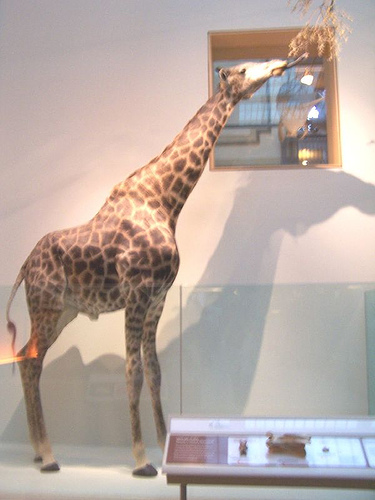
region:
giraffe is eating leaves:
[22, 58, 282, 451]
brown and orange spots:
[80, 110, 225, 329]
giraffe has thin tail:
[1, 249, 63, 336]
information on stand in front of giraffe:
[161, 412, 367, 466]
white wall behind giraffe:
[30, 66, 135, 177]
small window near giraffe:
[188, 30, 347, 165]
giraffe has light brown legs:
[122, 334, 168, 471]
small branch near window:
[268, 1, 333, 76]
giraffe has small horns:
[216, 68, 227, 83]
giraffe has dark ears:
[217, 73, 232, 110]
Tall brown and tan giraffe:
[3, 40, 318, 492]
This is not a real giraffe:
[5, 48, 311, 489]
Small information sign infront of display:
[148, 408, 370, 497]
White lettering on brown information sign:
[161, 422, 240, 472]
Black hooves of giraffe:
[24, 440, 165, 485]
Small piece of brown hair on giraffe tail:
[5, 319, 26, 366]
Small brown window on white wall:
[197, 16, 351, 196]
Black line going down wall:
[163, 283, 197, 415]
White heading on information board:
[163, 410, 373, 436]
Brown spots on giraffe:
[13, 64, 195, 452]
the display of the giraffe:
[1, 35, 316, 444]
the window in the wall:
[196, 28, 343, 176]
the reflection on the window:
[285, 65, 322, 113]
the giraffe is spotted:
[41, 148, 290, 307]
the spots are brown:
[33, 129, 204, 285]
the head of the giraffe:
[203, 43, 283, 121]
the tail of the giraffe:
[1, 283, 28, 370]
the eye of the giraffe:
[234, 67, 250, 78]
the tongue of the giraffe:
[282, 50, 316, 83]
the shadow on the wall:
[203, 196, 324, 278]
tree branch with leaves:
[283, 0, 352, 70]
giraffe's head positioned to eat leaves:
[215, 56, 288, 103]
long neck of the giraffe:
[123, 101, 243, 215]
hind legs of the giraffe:
[15, 298, 73, 468]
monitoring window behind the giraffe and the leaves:
[209, 32, 339, 169]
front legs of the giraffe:
[122, 278, 167, 475]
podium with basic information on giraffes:
[162, 415, 374, 498]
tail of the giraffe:
[3, 265, 25, 371]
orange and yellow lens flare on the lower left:
[0, 328, 42, 364]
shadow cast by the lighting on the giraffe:
[176, 169, 372, 417]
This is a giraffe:
[34, 192, 191, 365]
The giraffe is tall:
[122, 152, 180, 396]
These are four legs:
[1, 335, 235, 485]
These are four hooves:
[18, 447, 126, 483]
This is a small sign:
[215, 375, 369, 468]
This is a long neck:
[158, 126, 256, 204]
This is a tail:
[8, 257, 24, 347]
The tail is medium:
[1, 308, 29, 343]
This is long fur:
[4, 330, 39, 355]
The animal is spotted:
[44, 256, 97, 290]